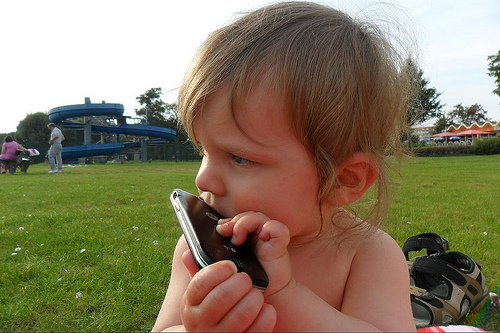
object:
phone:
[169, 188, 269, 290]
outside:
[0, 0, 495, 122]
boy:
[148, 0, 422, 333]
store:
[432, 120, 500, 147]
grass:
[60, 212, 115, 250]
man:
[45, 123, 67, 175]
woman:
[0, 134, 27, 174]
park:
[0, 0, 495, 330]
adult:
[47, 123, 66, 175]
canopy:
[410, 120, 500, 145]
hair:
[174, 0, 422, 245]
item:
[395, 228, 486, 330]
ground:
[385, 157, 499, 285]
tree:
[133, 87, 179, 130]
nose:
[190, 162, 229, 195]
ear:
[317, 150, 382, 207]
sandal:
[401, 231, 490, 330]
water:
[80, 151, 128, 164]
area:
[0, 167, 154, 333]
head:
[171, 0, 420, 246]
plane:
[175, 189, 269, 288]